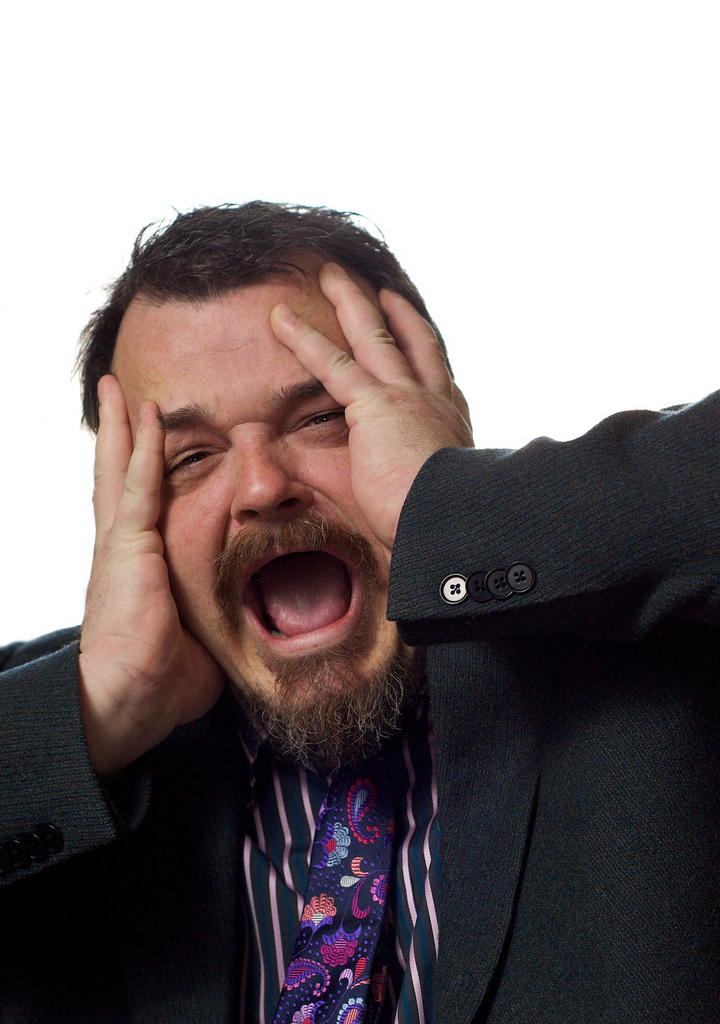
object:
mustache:
[214, 510, 383, 634]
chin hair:
[237, 641, 425, 772]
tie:
[268, 785, 402, 1021]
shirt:
[55, 655, 687, 1022]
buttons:
[439, 561, 535, 607]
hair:
[79, 198, 432, 434]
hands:
[79, 265, 474, 779]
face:
[111, 250, 446, 759]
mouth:
[240, 544, 360, 659]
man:
[3, 200, 715, 1014]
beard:
[230, 651, 414, 768]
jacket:
[0, 400, 718, 1022]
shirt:
[236, 699, 439, 1016]